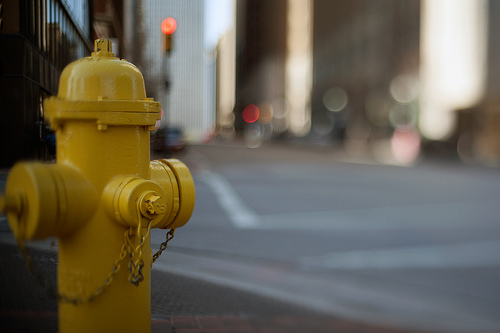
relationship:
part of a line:
[426, 232, 448, 265] [314, 230, 484, 275]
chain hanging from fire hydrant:
[92, 193, 186, 307] [0, 37, 197, 333]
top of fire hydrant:
[92, 34, 114, 55] [0, 37, 197, 333]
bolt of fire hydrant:
[146, 193, 169, 217] [0, 37, 197, 333]